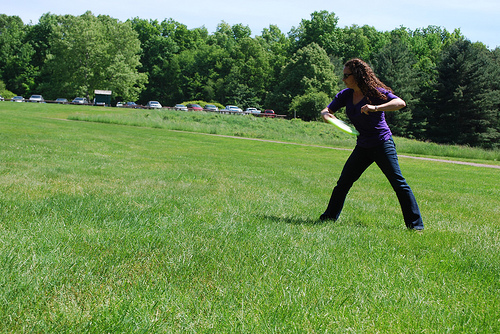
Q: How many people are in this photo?
A: 1.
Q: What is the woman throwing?
A: A frisbee.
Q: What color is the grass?
A: Green.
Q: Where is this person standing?
A: In a field.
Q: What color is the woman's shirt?
A: Purple.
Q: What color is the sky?
A: Blue.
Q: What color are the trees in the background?
A: Green.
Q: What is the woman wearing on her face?
A: Sunglasses.